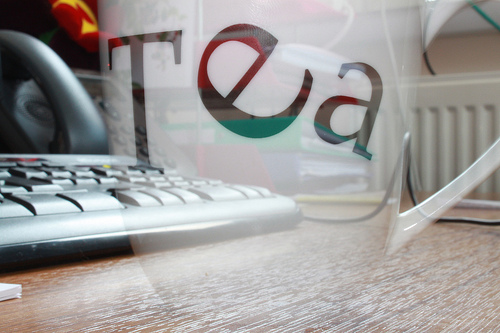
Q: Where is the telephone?
A: Behind the keyboard.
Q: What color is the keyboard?
A: Black.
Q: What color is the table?
A: Brown.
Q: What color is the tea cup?
A: White.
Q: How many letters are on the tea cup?
A: Three.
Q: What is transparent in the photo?
A: The Tea Cup.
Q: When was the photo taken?
A: Daytime.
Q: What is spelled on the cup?
A: Tea.